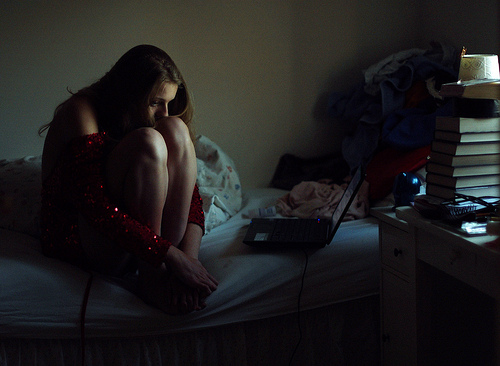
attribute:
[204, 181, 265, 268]
bed sheet — white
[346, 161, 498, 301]
books — hardcover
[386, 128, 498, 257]
fan — dark blue and circular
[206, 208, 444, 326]
desk — white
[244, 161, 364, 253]
laptop — black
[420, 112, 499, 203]
books — stacked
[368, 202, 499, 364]
wooden desk — white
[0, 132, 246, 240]
blanket — white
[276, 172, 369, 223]
clothes — pink